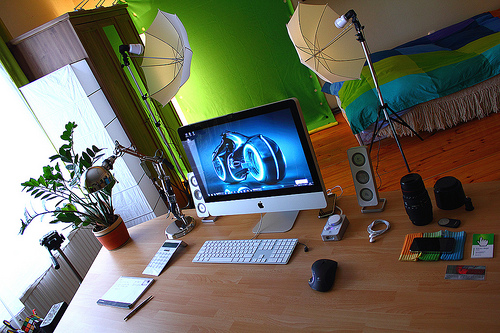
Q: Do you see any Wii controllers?
A: No, there are no Wii controllers.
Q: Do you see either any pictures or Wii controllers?
A: No, there are no Wii controllers or pictures.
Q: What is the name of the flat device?
A: The device is a computer monitor.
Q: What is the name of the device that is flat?
A: The device is a computer monitor.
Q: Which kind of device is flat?
A: The device is a computer monitor.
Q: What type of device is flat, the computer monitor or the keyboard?
A: The computer monitor is flat.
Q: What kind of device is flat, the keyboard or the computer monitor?
A: The computer monitor is flat.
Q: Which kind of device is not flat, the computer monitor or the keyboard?
A: The keyboard is not flat.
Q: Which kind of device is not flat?
A: The device is a keyboard.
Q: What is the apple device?
A: The device is a computer monitor.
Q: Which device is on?
A: The device is a computer monitor.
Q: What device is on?
A: The device is a computer monitor.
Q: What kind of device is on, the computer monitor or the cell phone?
A: The computer monitor is on.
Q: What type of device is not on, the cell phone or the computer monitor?
A: The cell phone is not on.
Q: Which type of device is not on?
A: The device is a cell phone.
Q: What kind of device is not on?
A: The device is a cell phone.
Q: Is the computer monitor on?
A: Yes, the computer monitor is on.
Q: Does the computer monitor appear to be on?
A: Yes, the computer monitor is on.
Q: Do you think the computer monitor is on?
A: Yes, the computer monitor is on.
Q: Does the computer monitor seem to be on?
A: Yes, the computer monitor is on.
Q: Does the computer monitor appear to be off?
A: No, the computer monitor is on.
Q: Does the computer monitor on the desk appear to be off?
A: No, the computer monitor is on.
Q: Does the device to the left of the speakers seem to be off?
A: No, the computer monitor is on.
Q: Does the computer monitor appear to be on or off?
A: The computer monitor is on.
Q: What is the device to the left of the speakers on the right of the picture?
A: The device is a computer monitor.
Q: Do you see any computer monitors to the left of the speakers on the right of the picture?
A: Yes, there is a computer monitor to the left of the speakers.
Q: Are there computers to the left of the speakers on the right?
A: No, there is a computer monitor to the left of the speakers.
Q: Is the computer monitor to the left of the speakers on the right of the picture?
A: Yes, the computer monitor is to the left of the speakers.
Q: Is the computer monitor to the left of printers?
A: No, the computer monitor is to the left of the speakers.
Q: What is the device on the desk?
A: The device is a computer monitor.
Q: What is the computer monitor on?
A: The computer monitor is on the desk.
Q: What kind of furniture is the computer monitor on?
A: The computer monitor is on the desk.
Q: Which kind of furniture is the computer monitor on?
A: The computer monitor is on the desk.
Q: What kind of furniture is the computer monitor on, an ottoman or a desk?
A: The computer monitor is on a desk.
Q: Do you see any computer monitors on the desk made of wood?
A: Yes, there is a computer monitor on the desk.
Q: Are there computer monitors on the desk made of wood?
A: Yes, there is a computer monitor on the desk.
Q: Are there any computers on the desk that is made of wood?
A: No, there is a computer monitor on the desk.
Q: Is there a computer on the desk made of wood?
A: No, there is a computer monitor on the desk.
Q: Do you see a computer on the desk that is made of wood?
A: No, there is a computer monitor on the desk.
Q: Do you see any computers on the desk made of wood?
A: No, there is a computer monitor on the desk.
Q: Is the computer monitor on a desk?
A: Yes, the computer monitor is on a desk.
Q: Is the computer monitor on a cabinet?
A: No, the computer monitor is on a desk.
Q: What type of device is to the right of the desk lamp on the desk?
A: The device is a computer monitor.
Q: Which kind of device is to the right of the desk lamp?
A: The device is a computer monitor.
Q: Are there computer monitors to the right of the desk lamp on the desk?
A: Yes, there is a computer monitor to the right of the desk lamp.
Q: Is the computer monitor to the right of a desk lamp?
A: Yes, the computer monitor is to the right of a desk lamp.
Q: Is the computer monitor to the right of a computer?
A: No, the computer monitor is to the right of a desk lamp.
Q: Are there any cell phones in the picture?
A: Yes, there is a cell phone.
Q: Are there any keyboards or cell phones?
A: Yes, there is a cell phone.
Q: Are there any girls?
A: No, there are no girls.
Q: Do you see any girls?
A: No, there are no girls.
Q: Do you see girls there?
A: No, there are no girls.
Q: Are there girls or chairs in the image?
A: No, there are no girls or chairs.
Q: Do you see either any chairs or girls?
A: No, there are no girls or chairs.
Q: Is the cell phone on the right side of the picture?
A: Yes, the cell phone is on the right of the image.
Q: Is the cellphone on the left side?
A: No, the cellphone is on the right of the image.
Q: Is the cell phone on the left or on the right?
A: The cell phone is on the right of the image.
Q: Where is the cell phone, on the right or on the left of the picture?
A: The cell phone is on the right of the image.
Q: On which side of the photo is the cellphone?
A: The cellphone is on the right of the image.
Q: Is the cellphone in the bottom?
A: Yes, the cellphone is in the bottom of the image.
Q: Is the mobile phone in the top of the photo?
A: No, the mobile phone is in the bottom of the image.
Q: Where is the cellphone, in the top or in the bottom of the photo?
A: The cellphone is in the bottom of the image.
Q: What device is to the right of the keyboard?
A: The device is a cell phone.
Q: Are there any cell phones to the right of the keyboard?
A: Yes, there is a cell phone to the right of the keyboard.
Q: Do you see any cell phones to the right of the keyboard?
A: Yes, there is a cell phone to the right of the keyboard.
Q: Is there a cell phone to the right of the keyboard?
A: Yes, there is a cell phone to the right of the keyboard.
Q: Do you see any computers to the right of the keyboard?
A: No, there is a cell phone to the right of the keyboard.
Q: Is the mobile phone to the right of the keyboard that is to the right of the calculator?
A: Yes, the mobile phone is to the right of the keyboard.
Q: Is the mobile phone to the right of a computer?
A: No, the mobile phone is to the right of the keyboard.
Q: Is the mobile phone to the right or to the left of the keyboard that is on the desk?
A: The mobile phone is to the right of the keyboard.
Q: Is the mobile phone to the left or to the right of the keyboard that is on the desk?
A: The mobile phone is to the right of the keyboard.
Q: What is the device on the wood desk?
A: The device is a cell phone.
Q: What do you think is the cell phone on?
A: The cell phone is on the desk.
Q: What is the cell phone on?
A: The cell phone is on the desk.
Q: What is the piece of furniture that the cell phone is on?
A: The piece of furniture is a desk.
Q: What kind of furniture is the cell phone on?
A: The cell phone is on the desk.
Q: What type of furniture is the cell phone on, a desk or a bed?
A: The cell phone is on a desk.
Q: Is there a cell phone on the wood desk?
A: Yes, there is a cell phone on the desk.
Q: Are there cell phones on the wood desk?
A: Yes, there is a cell phone on the desk.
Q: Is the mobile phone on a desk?
A: Yes, the mobile phone is on a desk.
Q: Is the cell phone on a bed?
A: No, the cell phone is on a desk.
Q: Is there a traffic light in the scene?
A: No, there are no traffic lights.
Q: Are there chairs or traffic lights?
A: No, there are no traffic lights or chairs.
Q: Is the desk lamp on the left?
A: Yes, the desk lamp is on the left of the image.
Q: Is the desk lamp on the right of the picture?
A: No, the desk lamp is on the left of the image.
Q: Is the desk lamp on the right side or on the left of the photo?
A: The desk lamp is on the left of the image.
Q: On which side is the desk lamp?
A: The desk lamp is on the left of the image.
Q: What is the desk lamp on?
A: The desk lamp is on the desk.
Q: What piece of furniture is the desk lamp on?
A: The desk lamp is on the desk.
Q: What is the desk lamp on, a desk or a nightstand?
A: The desk lamp is on a desk.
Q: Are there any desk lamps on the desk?
A: Yes, there is a desk lamp on the desk.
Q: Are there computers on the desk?
A: No, there is a desk lamp on the desk.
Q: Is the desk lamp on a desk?
A: Yes, the desk lamp is on a desk.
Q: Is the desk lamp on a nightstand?
A: No, the desk lamp is on a desk.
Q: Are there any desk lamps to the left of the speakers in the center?
A: Yes, there is a desk lamp to the left of the speakers.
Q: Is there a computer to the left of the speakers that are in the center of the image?
A: No, there is a desk lamp to the left of the speakers.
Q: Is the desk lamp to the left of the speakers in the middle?
A: Yes, the desk lamp is to the left of the speakers.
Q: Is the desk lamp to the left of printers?
A: No, the desk lamp is to the left of the speakers.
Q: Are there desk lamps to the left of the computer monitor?
A: Yes, there is a desk lamp to the left of the computer monitor.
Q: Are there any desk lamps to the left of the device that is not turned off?
A: Yes, there is a desk lamp to the left of the computer monitor.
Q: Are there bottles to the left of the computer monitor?
A: No, there is a desk lamp to the left of the computer monitor.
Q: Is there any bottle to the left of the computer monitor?
A: No, there is a desk lamp to the left of the computer monitor.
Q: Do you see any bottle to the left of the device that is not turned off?
A: No, there is a desk lamp to the left of the computer monitor.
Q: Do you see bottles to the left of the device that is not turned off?
A: No, there is a desk lamp to the left of the computer monitor.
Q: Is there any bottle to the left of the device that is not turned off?
A: No, there is a desk lamp to the left of the computer monitor.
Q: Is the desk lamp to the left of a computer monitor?
A: Yes, the desk lamp is to the left of a computer monitor.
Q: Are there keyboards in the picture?
A: Yes, there is a keyboard.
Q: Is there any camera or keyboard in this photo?
A: Yes, there is a keyboard.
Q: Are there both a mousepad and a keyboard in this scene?
A: No, there is a keyboard but no mouse pads.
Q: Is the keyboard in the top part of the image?
A: No, the keyboard is in the bottom of the image.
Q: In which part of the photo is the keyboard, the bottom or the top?
A: The keyboard is in the bottom of the image.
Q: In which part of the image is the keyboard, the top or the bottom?
A: The keyboard is in the bottom of the image.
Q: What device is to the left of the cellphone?
A: The device is a keyboard.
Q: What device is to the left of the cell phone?
A: The device is a keyboard.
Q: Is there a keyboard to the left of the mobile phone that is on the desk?
A: Yes, there is a keyboard to the left of the cell phone.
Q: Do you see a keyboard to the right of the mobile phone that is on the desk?
A: No, the keyboard is to the left of the mobile phone.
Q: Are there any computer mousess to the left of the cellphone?
A: No, there is a keyboard to the left of the cellphone.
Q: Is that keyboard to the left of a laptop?
A: No, the keyboard is to the left of the cell phone.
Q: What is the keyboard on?
A: The keyboard is on the desk.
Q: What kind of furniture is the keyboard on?
A: The keyboard is on the desk.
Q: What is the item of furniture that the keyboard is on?
A: The piece of furniture is a desk.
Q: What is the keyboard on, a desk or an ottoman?
A: The keyboard is on a desk.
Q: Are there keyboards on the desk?
A: Yes, there is a keyboard on the desk.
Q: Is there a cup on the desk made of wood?
A: No, there is a keyboard on the desk.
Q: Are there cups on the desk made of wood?
A: No, there is a keyboard on the desk.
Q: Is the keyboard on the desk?
A: Yes, the keyboard is on the desk.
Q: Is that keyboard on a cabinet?
A: No, the keyboard is on the desk.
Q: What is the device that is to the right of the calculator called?
A: The device is a keyboard.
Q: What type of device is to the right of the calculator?
A: The device is a keyboard.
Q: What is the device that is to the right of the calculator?
A: The device is a keyboard.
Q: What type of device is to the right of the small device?
A: The device is a keyboard.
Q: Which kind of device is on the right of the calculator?
A: The device is a keyboard.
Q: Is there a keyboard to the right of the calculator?
A: Yes, there is a keyboard to the right of the calculator.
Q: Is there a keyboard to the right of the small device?
A: Yes, there is a keyboard to the right of the calculator.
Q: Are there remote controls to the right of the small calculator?
A: No, there is a keyboard to the right of the calculator.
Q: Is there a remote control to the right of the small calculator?
A: No, there is a keyboard to the right of the calculator.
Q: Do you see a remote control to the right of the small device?
A: No, there is a keyboard to the right of the calculator.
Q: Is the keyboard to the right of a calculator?
A: Yes, the keyboard is to the right of a calculator.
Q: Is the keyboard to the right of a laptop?
A: No, the keyboard is to the right of a calculator.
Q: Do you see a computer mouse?
A: Yes, there is a computer mouse.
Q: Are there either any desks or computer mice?
A: Yes, there is a computer mouse.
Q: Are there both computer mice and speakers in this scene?
A: Yes, there are both a computer mouse and a speaker.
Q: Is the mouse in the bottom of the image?
A: Yes, the mouse is in the bottom of the image.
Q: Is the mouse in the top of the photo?
A: No, the mouse is in the bottom of the image.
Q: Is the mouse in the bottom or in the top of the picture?
A: The mouse is in the bottom of the image.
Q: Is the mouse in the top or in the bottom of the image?
A: The mouse is in the bottom of the image.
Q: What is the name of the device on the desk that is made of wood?
A: The device is a computer mouse.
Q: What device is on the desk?
A: The device is a computer mouse.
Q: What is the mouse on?
A: The mouse is on the desk.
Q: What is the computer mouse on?
A: The mouse is on the desk.